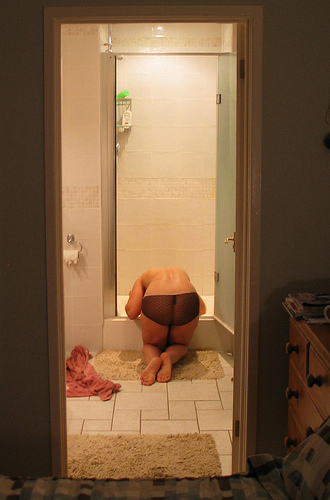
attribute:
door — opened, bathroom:
[44, 9, 264, 495]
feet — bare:
[136, 349, 175, 388]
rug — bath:
[93, 336, 227, 383]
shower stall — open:
[100, 49, 206, 322]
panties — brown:
[138, 286, 208, 328]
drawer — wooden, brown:
[286, 316, 308, 380]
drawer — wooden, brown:
[305, 341, 319, 418]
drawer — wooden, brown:
[286, 358, 319, 439]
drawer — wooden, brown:
[284, 404, 305, 459]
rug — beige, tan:
[66, 432, 223, 478]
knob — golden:
[223, 229, 236, 253]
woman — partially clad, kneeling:
[124, 265, 206, 386]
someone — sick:
[124, 265, 207, 386]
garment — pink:
[66, 345, 121, 402]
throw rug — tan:
[64, 433, 222, 479]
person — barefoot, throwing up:
[124, 264, 207, 386]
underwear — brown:
[139, 291, 200, 328]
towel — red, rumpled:
[65, 344, 121, 402]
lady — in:
[114, 258, 221, 392]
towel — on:
[67, 342, 120, 411]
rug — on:
[74, 421, 215, 471]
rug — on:
[83, 427, 215, 467]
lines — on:
[159, 384, 175, 420]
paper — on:
[63, 244, 79, 268]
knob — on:
[219, 227, 240, 251]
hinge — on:
[230, 418, 245, 437]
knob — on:
[280, 339, 301, 357]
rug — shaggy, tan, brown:
[66, 427, 225, 480]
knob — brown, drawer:
[279, 337, 301, 359]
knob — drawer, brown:
[303, 371, 325, 390]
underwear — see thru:
[137, 290, 203, 329]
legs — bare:
[131, 309, 204, 384]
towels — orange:
[62, 345, 120, 403]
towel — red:
[64, 344, 122, 409]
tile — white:
[163, 397, 200, 421]